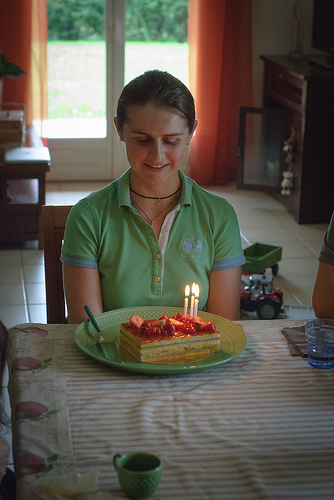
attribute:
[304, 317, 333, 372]
glass — blue, small, clear, drinking glass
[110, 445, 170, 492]
coffee cup — green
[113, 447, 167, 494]
coffee mug — green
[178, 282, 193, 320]
candle — small, white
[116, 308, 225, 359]
slice — cake, large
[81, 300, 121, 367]
silverware — green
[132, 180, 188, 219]
necklace — girl's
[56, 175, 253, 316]
shirt — green, short sleeved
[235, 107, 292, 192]
door — cabinet's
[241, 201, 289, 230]
piece — tile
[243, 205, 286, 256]
tile — white, floor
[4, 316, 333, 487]
tablecloth — pink, white, striped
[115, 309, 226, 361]
cake — delicious, strawberry, birthday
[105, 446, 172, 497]
teacup — small, green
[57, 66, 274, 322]
woman — brunette, smiling, getting ready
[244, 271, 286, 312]
truck — red, toy, child's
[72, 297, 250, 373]
plate — green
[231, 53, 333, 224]
cabinet — brown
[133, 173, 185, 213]
neck — woman's